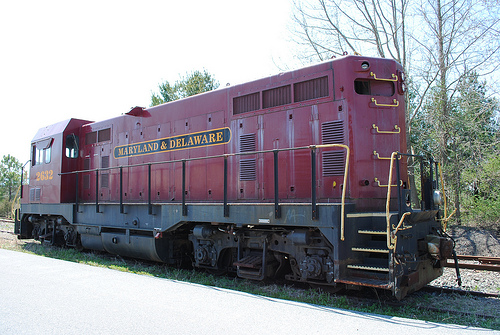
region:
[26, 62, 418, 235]
this is a train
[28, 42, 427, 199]
the train is red in color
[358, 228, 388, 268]
this is the staircase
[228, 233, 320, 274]
the wheels are metallic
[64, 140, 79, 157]
this is the window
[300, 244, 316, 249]
the wheels are black in color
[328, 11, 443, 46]
the trees are tall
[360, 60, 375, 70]
the light is offf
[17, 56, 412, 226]
the train is parked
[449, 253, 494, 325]
these are the trains rails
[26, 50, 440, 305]
the train is red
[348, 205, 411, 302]
train has black steps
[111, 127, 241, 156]
maryland and delaware are written on train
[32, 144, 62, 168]
red train has windows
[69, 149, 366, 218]
train has black rails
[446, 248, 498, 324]
red train is on track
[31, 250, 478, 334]
red train is near grass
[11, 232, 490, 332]
grass is green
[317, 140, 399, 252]
train rail is yellow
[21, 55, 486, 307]
red train is large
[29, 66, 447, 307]
A red train car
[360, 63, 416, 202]
Yellow rungs on a red train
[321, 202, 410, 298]
black and yellow steps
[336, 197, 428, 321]
black and yellow steps on a train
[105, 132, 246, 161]
yellow letters on a black background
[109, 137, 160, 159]
The yellow word "MARYLAND"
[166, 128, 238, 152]
The yellow word "DELAWARE"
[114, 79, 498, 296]
A train on train tracks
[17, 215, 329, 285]
The wheels of a train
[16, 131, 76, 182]
The windows of a train car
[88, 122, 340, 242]
Red train car on tracks.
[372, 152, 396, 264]
Yellow railing near stairs.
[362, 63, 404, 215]
Yellow handles on back of train.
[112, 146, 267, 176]
Maryland & delaware written on side.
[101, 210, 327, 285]
Bottom of train is black.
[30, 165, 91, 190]
2632 written in yellow on side.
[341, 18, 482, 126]
Large tree with no leaves near train.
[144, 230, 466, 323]
Gravel under and beside tracks.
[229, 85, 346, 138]
Vents in the side of the train car.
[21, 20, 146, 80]
Sky is light in color.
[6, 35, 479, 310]
A red and black train engine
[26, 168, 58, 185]
Yellow painted numbers 2632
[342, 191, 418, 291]
Steps on train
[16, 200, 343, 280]
Black undercarriage of train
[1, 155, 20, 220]
A green tree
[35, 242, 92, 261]
A patch of green grass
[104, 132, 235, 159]
Black and yellow writing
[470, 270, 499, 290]
A grey patch of gravel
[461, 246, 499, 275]
Rusty train tracks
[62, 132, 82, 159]
A small window